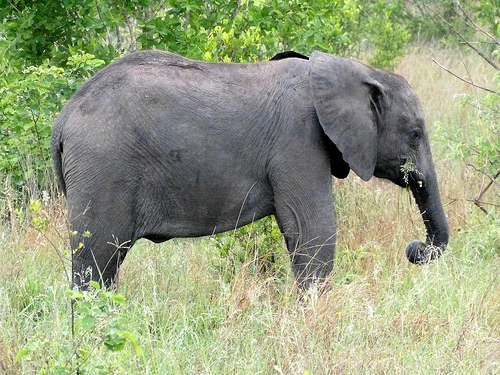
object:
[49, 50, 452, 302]
elephant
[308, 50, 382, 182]
right ear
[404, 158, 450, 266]
trunk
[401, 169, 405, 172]
leaves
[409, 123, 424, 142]
right eye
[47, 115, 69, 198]
tail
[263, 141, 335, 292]
front leg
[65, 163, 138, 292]
hind leg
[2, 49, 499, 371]
grass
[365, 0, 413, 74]
trees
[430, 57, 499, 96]
branches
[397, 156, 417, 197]
mouth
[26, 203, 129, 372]
tree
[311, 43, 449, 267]
head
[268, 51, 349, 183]
left ear